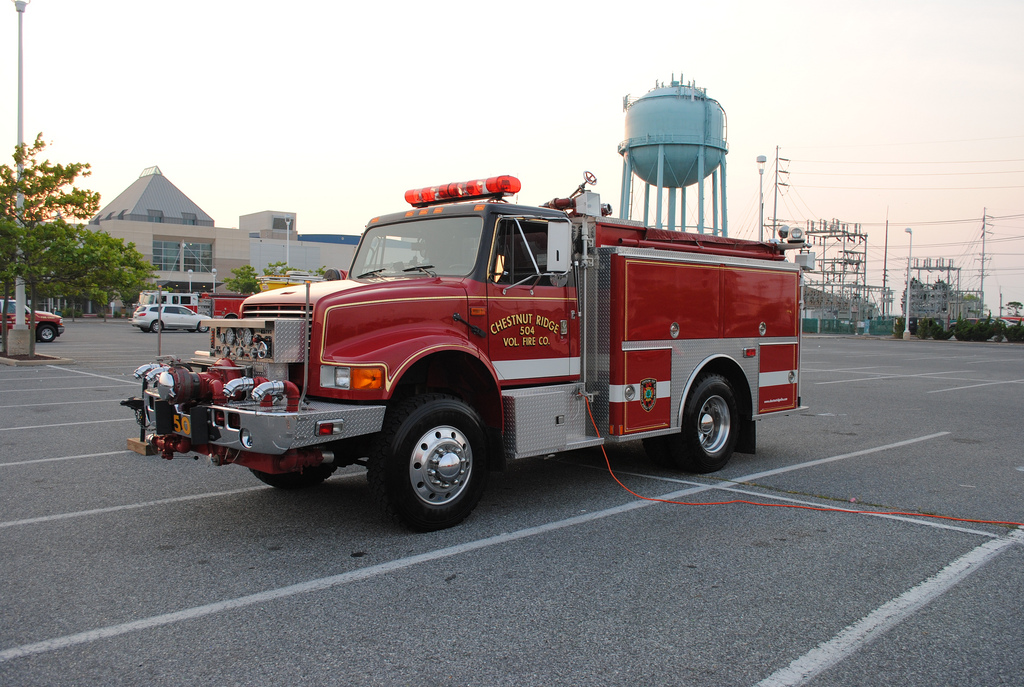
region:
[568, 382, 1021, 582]
long red hose leading from truck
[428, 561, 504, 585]
tiny spot on the ground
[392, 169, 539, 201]
red siren on top of truck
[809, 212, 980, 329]
tall electrical grid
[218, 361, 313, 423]
silver water outlets on front of truck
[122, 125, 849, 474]
shiny red fire truck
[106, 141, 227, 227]
domed silver roof on building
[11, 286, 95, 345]
red truck parked in the space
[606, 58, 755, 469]
Water tower behind a fire engine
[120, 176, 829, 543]
A red fire engine with orange lights on top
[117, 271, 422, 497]
The front end of a fire engine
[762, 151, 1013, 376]
Electrical transformer relay yard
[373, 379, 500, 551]
Front tire of a fire engine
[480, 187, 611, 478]
Driver side door of fire engine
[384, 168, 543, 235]
Orange lights on top of fire truck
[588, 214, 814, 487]
Compartment doors on a fire engine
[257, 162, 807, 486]
old red fire truck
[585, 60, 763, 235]
green water tower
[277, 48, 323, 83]
white clouds in blue sky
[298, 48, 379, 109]
white clouds in blue sky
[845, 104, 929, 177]
white clouds in blue sky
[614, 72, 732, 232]
a gray metallic water tower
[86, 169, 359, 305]
a building with a triangular roof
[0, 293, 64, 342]
a parked red car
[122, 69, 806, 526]
a red firetruck parked in front of a water tower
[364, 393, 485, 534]
a black tire with a shiny hubcap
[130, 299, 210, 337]
a white parked car with red lights on the back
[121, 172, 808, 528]
red lights on top of a firetruck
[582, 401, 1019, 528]
a red wire on the concrete floor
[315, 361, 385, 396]
a white and orange light